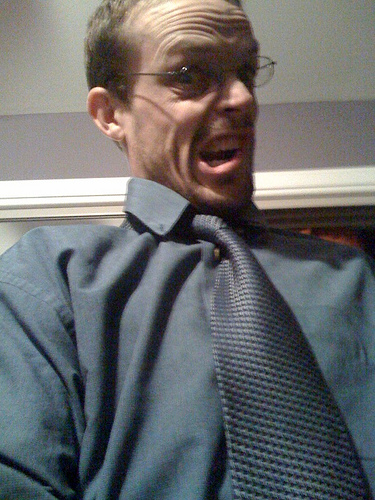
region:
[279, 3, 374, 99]
A gray colored ceiling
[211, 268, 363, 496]
A blue and black colored tie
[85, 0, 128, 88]
Brown hair on a man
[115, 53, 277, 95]
Glasses on a man's face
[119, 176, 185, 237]
The collar of a blue suit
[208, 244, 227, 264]
The black button of a blue suit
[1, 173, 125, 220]
White trim around a doorway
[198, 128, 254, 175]
A man's mouth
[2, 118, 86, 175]
A dark gray wall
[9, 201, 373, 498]
A blue colored suit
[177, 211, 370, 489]
man wearing a blue patterned tie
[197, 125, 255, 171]
man making a funny face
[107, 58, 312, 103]
man is wearing glasses with circular frames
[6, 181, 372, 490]
man wearing a blue dress shirt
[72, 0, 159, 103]
short and brown hair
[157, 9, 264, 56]
wrinkles on the man's forehead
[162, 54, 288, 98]
man's eyes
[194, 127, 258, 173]
man's mouth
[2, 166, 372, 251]
the white door frame behind the man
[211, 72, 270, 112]
the man's nose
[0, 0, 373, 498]
indeterminate aged man strangled by tie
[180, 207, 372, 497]
bulky blue tie effecting [metaphorical] strangulation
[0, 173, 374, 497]
blue button down shirt, high collar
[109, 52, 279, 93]
narrow, thin metal hupster glasses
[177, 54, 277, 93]
the oval lenses of thin metal hupster glasses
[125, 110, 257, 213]
some kind of indeterminate facial hair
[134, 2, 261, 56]
coerced forehead wrinklesz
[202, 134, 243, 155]
straight well cared for top teeth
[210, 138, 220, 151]
pointy eye tooth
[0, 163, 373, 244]
a bit of white wainscoting, or at least wooden trim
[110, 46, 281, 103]
Man is wearing glasses.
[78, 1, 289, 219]
Man is making strange face.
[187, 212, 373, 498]
Man is wearing blue tie.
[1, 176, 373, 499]
Man is wearing a blue shirt.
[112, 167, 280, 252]
Man's shirt has a collar.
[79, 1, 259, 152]
Man's hair is short.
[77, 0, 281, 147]
Man's hair is neatly styled.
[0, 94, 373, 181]
Wall above doorway is gray.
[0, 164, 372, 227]
Door trim is white.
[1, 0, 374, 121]
Ceiling above man is white.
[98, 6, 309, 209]
Man is making a funny face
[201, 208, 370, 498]
Man is wearing a tie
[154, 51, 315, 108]
Man is wearing eyeglasses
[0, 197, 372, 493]
Man is wearing a light blue shirt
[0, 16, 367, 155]
Wall in background is gray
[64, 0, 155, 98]
Mans hair is brown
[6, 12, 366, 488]
Photo is slightly grainy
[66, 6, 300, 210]
Man is looking at the camera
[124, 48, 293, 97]
Man has on round shaped eyeglasses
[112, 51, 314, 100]
Man's eyeglasses has a black frame